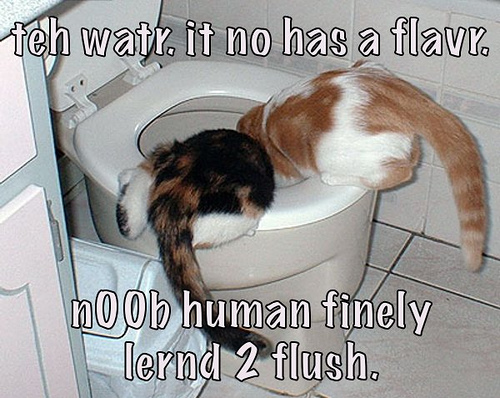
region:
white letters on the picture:
[5, 12, 492, 392]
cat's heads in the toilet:
[111, 50, 494, 365]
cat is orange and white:
[229, 57, 498, 297]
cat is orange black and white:
[100, 128, 299, 360]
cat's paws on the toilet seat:
[102, 162, 262, 256]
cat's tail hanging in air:
[412, 73, 493, 277]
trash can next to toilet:
[62, 230, 214, 394]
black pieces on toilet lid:
[62, 70, 95, 96]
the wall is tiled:
[161, 1, 492, 255]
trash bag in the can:
[86, 322, 221, 395]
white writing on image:
[0, 13, 492, 74]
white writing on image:
[46, 268, 437, 391]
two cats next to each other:
[105, 60, 476, 272]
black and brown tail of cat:
[145, 214, 250, 319]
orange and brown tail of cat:
[393, 86, 479, 242]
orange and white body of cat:
[250, 64, 415, 188]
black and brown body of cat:
[150, 152, 263, 216]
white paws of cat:
[317, 160, 409, 197]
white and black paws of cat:
[98, 172, 158, 232]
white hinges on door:
[25, 201, 71, 261]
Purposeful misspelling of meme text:
[10, 13, 490, 60]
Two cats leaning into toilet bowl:
[127, 60, 487, 355]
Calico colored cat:
[115, 131, 275, 348]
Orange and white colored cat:
[244, 59, 492, 272]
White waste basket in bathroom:
[67, 233, 204, 397]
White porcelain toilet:
[49, 10, 370, 386]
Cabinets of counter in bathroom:
[1, 33, 91, 395]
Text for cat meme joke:
[10, 19, 488, 379]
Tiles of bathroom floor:
[333, 223, 495, 397]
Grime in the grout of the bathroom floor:
[238, 376, 340, 396]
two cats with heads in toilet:
[76, 60, 499, 281]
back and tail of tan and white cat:
[250, 65, 488, 275]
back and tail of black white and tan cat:
[118, 125, 268, 358]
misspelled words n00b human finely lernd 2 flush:
[65, 285, 435, 384]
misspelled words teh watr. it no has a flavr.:
[9, 11, 493, 63]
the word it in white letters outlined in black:
[183, 14, 217, 61]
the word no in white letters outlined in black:
[222, 23, 274, 60]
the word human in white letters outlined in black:
[180, 285, 313, 334]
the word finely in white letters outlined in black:
[319, 282, 435, 339]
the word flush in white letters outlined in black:
[269, 337, 371, 387]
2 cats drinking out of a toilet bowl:
[96, 62, 491, 289]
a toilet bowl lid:
[40, 0, 167, 140]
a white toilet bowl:
[85, 26, 421, 374]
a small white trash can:
[66, 245, 201, 395]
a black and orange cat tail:
[151, 212, 271, 362]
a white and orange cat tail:
[410, 108, 494, 279]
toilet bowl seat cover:
[77, 48, 401, 229]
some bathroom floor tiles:
[375, 245, 499, 387]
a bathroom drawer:
[0, 1, 55, 395]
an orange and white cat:
[239, 58, 489, 270]